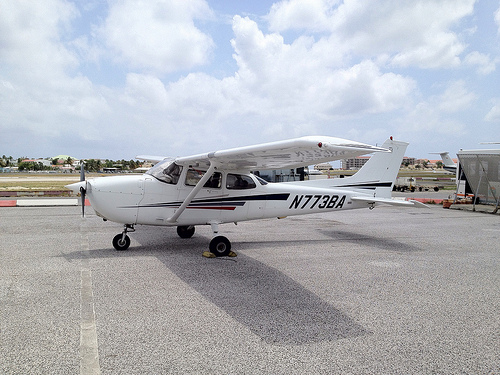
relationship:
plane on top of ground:
[62, 131, 432, 256] [2, 194, 498, 374]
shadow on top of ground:
[60, 223, 428, 344] [2, 194, 498, 374]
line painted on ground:
[77, 213, 105, 374] [2, 194, 498, 374]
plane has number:
[62, 131, 432, 256] [289, 195, 346, 209]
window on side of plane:
[225, 171, 256, 190] [62, 131, 432, 256]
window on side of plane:
[185, 167, 224, 189] [62, 131, 432, 256]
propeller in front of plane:
[79, 160, 87, 215] [62, 131, 432, 256]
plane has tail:
[62, 131, 432, 256] [353, 138, 411, 192]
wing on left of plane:
[176, 134, 394, 171] [62, 131, 432, 256]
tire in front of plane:
[110, 233, 130, 252] [62, 131, 432, 256]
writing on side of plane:
[290, 193, 348, 209] [62, 131, 432, 256]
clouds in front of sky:
[0, 0, 499, 153] [56, 0, 500, 128]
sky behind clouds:
[56, 0, 500, 128] [0, 0, 499, 153]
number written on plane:
[289, 195, 346, 209] [62, 131, 432, 256]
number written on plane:
[311, 195, 323, 211] [62, 131, 432, 256]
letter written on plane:
[289, 194, 305, 209] [62, 131, 432, 256]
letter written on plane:
[338, 195, 347, 210] [62, 131, 432, 256]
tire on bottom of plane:
[211, 235, 232, 257] [62, 131, 432, 256]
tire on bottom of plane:
[176, 224, 197, 238] [62, 131, 432, 256]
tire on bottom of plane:
[110, 233, 130, 252] [62, 131, 432, 256]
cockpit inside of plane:
[146, 159, 182, 189] [62, 131, 432, 256]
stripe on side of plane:
[168, 205, 237, 211] [62, 131, 432, 256]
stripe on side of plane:
[120, 200, 246, 208] [62, 131, 432, 256]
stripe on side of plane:
[153, 192, 291, 201] [62, 131, 432, 256]